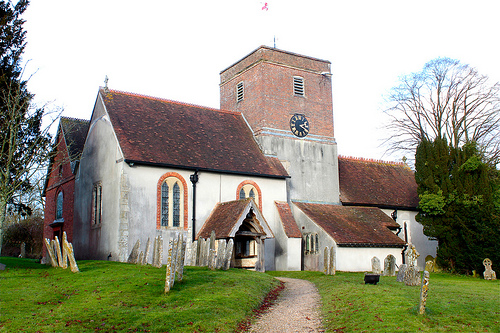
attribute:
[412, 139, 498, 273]
tree — large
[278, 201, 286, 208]
brick — red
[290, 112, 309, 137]
clock — black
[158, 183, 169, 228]
window — part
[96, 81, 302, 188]
roof — red, brick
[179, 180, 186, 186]
brick — red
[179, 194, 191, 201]
brick — red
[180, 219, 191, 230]
brick — red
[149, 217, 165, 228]
brick — red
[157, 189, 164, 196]
brick — red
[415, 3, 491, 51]
sky — cloudy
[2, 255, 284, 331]
grass — part 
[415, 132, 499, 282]
tree — thick, green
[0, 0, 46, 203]
tree — thick, green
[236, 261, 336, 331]
path — tar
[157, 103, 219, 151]
brick — red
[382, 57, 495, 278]
trees — bare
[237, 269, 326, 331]
path — tar